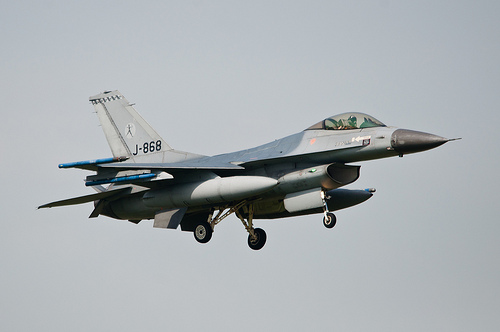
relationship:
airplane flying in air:
[36, 89, 462, 250] [0, 1, 500, 331]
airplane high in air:
[36, 89, 462, 250] [0, 1, 500, 331]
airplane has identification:
[36, 89, 462, 250] [132, 139, 163, 157]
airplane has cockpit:
[36, 89, 462, 250] [308, 111, 388, 130]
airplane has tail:
[36, 89, 462, 250] [89, 87, 211, 177]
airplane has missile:
[36, 89, 462, 250] [90, 174, 280, 219]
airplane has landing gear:
[36, 89, 462, 250] [193, 197, 250, 243]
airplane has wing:
[36, 89, 462, 250] [57, 154, 245, 186]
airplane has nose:
[36, 89, 462, 250] [388, 127, 463, 158]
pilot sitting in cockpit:
[347, 114, 357, 128] [308, 111, 388, 130]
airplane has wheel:
[36, 89, 462, 250] [193, 219, 213, 243]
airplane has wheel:
[36, 89, 462, 250] [248, 226, 268, 250]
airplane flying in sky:
[36, 89, 462, 250] [1, 1, 499, 330]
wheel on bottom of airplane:
[193, 219, 213, 243] [36, 89, 462, 250]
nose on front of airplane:
[388, 127, 463, 158] [36, 89, 462, 250]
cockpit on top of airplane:
[308, 111, 388, 130] [36, 89, 462, 250]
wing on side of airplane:
[57, 154, 245, 186] [36, 89, 462, 250]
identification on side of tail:
[132, 139, 163, 157] [89, 87, 211, 177]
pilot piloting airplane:
[347, 114, 357, 128] [36, 89, 462, 250]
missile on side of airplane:
[90, 174, 280, 219] [36, 89, 462, 250]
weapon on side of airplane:
[59, 154, 130, 169] [36, 89, 462, 250]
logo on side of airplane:
[123, 121, 136, 140] [36, 89, 462, 250]